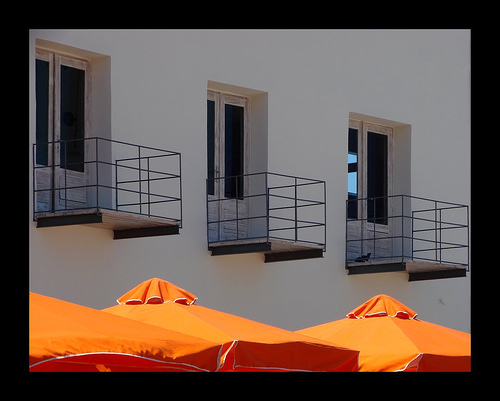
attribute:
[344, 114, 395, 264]
door — wood, black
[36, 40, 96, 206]
doors — apartment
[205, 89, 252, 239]
doors — apartment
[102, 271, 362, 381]
orange umbrella — red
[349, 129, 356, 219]
window — small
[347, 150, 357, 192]
light — blue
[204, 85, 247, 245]
door — wood, black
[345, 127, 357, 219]
window — small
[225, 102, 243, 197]
window — small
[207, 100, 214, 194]
window — small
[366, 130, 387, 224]
window — small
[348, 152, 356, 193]
light — blue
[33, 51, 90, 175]
window — small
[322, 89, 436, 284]
window — small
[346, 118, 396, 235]
window — small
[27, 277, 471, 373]
umbrella — orange, red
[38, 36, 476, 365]
house — painted white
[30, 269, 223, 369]
umbrella — red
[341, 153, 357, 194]
window — small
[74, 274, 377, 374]
umbrella — red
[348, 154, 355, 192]
light — blue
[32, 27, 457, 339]
house — unfinished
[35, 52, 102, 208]
doors — closed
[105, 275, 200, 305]
umbrella — red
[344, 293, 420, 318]
umbrella — red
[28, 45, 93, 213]
doors — apartment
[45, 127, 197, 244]
fences — black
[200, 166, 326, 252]
fences — black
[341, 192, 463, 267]
fences — black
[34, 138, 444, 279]
metal — black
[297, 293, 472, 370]
umbrella — opened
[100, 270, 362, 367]
umbrella — opened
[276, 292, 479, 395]
umbrellas — orange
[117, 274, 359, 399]
umbrellas — orange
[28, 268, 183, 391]
umbrellas — orange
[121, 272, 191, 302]
umbrella — red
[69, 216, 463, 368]
umbrella — red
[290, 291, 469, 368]
umbrella — red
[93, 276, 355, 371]
umbrella — red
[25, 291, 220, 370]
umbrella — red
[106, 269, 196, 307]
top — orange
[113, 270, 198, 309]
top — orange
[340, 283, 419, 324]
point — highest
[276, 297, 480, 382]
umbrella — orange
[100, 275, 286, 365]
umbrella — orange